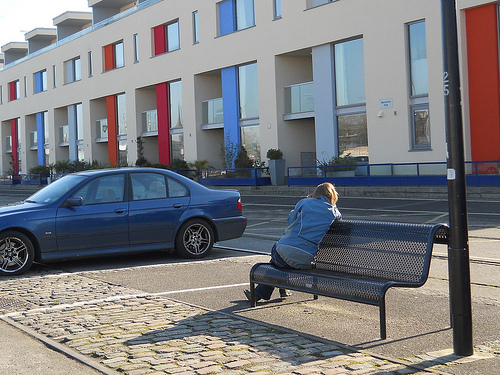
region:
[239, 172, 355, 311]
The woman is sitting on a bench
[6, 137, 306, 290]
The car is parked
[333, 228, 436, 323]
The bench is metal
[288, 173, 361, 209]
The woman has light hair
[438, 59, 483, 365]
The pole is metal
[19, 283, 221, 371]
The ground is made of stone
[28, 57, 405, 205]
The building has many balconies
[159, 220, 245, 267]
The car has black wheels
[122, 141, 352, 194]
The bushes are green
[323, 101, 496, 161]
The building has windows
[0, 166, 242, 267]
the car sitting in the parking lot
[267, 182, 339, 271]
a woman sitting on the bench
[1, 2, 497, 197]
a hotel with a colorful wall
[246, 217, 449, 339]
a metal bench with a mesh design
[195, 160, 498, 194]
a little metal fence in front of the building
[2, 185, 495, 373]
the parking lot of the hotel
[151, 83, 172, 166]
a red streak of the wall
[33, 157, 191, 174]
some plants in front of the building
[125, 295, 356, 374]
a shadow on the ground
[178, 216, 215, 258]
the wheel of the car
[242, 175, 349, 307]
Person sittin on metal bench.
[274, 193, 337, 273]
Person dressed in light blue jacket.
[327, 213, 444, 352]
Metal bench on sidewalk.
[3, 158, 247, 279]
Blue car parked in parking space.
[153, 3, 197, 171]
First and second floor windows on front of building.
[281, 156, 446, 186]
Blue metal railing along front of building.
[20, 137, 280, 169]
Shrubbery growing behind railing in front of building.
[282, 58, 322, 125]
Balcony on front of building.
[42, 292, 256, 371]
A brick paved sidewalk.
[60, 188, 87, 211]
Sideview mirror on blue car.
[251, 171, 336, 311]
the person on the bench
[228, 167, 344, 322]
the person is sitting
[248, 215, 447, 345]
the bench is modern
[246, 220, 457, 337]
the bench is metal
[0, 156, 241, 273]
the car is parked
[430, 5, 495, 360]
the pole is black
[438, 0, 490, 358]
the pole beside the bench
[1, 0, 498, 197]
the building near the car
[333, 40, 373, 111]
the window is closed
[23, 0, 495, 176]
the building is tan, blue, and red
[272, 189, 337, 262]
THE PERSON IS WEARING A JACKET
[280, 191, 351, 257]
THE PERSON'S JACKET IS BLUE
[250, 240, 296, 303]
THE PERSON IS WEARING JEANS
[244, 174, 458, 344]
THE PERSON IS SITTING ON A BENCH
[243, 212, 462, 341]
THE BENCH IS METAL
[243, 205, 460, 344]
THE BENCH IS BLACK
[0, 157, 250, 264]
THE CAR IS BLUE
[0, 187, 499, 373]
THE SIDEWALK IS CONCRETE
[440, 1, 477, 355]
THE POLE IS BLACK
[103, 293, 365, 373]
THE SHADOW IS ON THE GROUND